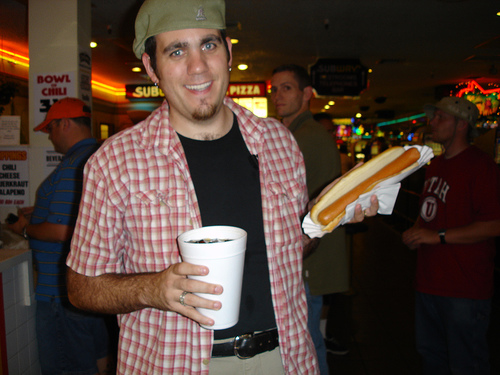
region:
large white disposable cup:
[169, 228, 252, 335]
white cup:
[168, 188, 269, 328]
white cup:
[117, 162, 281, 343]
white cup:
[161, 228, 246, 315]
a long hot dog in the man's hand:
[262, 107, 454, 238]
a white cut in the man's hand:
[154, 211, 274, 351]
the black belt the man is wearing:
[133, 322, 308, 358]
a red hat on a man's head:
[19, 93, 109, 143]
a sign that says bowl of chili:
[21, 58, 101, 133]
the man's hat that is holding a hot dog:
[122, 3, 239, 73]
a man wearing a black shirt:
[54, 0, 375, 374]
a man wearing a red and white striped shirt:
[49, 1, 325, 371]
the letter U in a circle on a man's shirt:
[408, 193, 458, 234]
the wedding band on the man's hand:
[172, 286, 197, 307]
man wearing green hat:
[128, 2, 233, 30]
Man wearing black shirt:
[201, 150, 243, 195]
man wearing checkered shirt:
[104, 155, 166, 211]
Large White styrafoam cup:
[213, 253, 238, 275]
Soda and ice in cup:
[189, 235, 234, 242]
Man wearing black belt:
[223, 339, 280, 355]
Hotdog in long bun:
[396, 159, 407, 170]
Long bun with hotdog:
[355, 166, 372, 179]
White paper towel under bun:
[377, 188, 395, 200]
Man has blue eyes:
[159, 42, 226, 57]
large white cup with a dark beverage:
[133, 205, 267, 350]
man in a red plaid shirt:
[53, 97, 338, 364]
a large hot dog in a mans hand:
[309, 133, 439, 254]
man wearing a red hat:
[25, 77, 113, 145]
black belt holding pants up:
[180, 307, 307, 369]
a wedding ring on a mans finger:
[161, 287, 211, 311]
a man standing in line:
[247, 49, 335, 152]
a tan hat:
[103, 0, 239, 52]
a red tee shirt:
[386, 128, 498, 292]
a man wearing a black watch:
[425, 215, 455, 258]